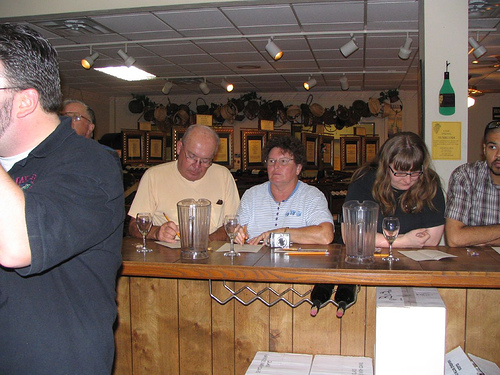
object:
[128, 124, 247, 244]
seated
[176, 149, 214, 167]
eye glasses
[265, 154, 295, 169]
eye glasses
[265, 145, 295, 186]
face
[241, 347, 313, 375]
wrap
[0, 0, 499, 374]
spectacle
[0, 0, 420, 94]
roof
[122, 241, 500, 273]
tabletop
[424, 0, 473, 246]
pillar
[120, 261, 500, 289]
bar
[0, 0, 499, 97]
ceiling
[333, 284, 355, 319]
wine bottle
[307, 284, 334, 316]
wine bottle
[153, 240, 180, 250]
paper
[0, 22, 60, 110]
hair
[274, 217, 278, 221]
buttons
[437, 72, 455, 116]
wine bottle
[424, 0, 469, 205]
wall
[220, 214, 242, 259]
glass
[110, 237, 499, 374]
table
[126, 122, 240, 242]
man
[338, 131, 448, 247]
person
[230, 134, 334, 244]
woman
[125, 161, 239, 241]
shirt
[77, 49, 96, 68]
light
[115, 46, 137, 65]
light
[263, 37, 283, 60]
light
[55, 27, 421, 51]
line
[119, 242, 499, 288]
counter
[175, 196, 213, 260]
pitcher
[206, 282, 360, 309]
rack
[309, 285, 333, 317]
wine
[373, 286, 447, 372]
box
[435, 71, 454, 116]
cozy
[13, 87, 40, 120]
ear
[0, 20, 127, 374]
bartender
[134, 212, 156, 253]
wine glass